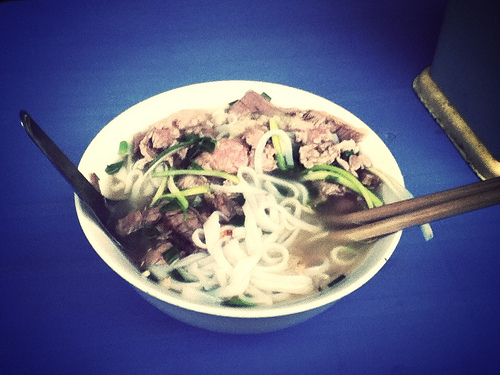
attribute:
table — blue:
[1, 17, 495, 375]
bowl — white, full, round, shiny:
[72, 57, 409, 370]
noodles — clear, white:
[108, 123, 368, 285]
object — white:
[403, 66, 499, 173]